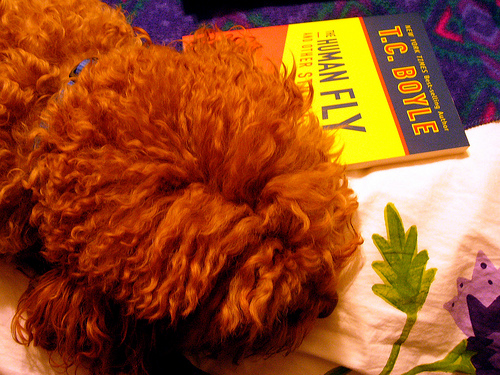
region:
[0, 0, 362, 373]
a red brown shaggy dog sleeping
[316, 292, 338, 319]
the dogs nose is black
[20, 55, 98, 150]
the dog is wearing a blue collar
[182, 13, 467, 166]
a book by T.C. Boyle is next to the dog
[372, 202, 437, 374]
the dog is laying on top of an embroidered sheet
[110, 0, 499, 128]
the book is on top of a knitted shawl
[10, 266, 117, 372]
the dogs ears are covered with long brown hair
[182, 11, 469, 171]
the books title is The Human Fly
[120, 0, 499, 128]
an embroidered purple, pink and green throw carpet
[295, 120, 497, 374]
the beige embroidered sheet has a plant design on it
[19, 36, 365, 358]
top of the dog's head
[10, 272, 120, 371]
the dog's paw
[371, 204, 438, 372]
a green appliqued leaf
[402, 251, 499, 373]
a lavender appliqued flower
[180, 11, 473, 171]
book by T.C. Boyle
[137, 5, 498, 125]
a purple blanket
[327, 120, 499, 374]
linen with appliqued leaves and flowers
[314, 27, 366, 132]
the title of the book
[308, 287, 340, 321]
the dog's nose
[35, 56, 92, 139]
the dog's collar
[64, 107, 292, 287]
red brown dog hair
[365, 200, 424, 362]
printed green plant leaf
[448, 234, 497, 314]
light purple portion of fllower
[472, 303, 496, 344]
dark purple portion of printed flower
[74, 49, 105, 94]
blue stitched dog collar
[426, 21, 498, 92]
blue, pink, and purple blanket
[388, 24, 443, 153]
T.C. Boyle print of authors name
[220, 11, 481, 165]
blue and yellow book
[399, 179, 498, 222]
white sheet part of sheet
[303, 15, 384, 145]
The Human Fly title of the book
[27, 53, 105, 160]
a blue collar on the dog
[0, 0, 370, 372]
a brown dog on the bed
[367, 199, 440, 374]
a green leaf pattern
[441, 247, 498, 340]
a purple flower pattern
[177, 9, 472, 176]
a book on the bed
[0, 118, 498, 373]
a white bedspread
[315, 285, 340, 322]
the nose of the dog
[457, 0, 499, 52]
a purple diamond pattern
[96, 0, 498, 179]
a purple bedspread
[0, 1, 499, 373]
a white and purple bedspread under the dog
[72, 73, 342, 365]
a very hairy dog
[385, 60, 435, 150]
boyle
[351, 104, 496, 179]
the book is yellow red and blue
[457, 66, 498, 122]
purple green and red blanket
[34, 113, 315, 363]
a very cute dog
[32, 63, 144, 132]
a blue dog collar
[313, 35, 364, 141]
the book says "human fly"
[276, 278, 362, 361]
the dog's eye and nose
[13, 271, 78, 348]
a brown dog's ear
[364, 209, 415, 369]
painted in green on white